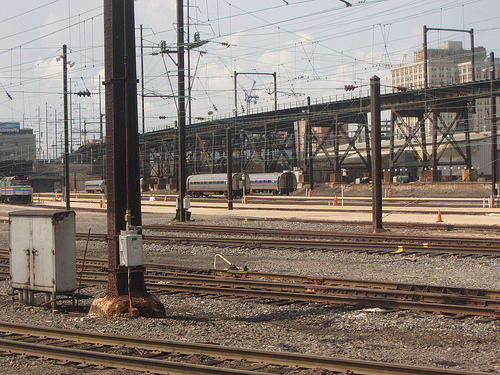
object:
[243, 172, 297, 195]
train car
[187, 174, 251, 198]
train car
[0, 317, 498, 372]
tracks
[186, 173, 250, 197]
passenger car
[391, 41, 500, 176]
building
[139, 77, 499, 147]
bridge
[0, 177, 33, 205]
train engine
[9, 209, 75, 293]
utility box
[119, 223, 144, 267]
meter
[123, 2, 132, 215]
pole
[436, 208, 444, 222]
pylon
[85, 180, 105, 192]
train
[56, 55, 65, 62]
spool insulator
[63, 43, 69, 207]
pole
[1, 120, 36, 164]
building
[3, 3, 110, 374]
left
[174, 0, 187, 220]
eletrical post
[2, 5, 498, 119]
power lines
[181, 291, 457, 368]
stones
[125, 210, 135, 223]
post clamp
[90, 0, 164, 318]
pole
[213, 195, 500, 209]
guard rail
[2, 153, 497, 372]
train yard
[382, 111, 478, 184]
trestle supports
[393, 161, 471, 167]
sills